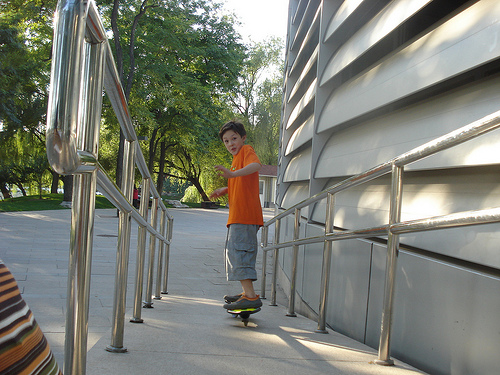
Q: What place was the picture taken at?
A: It was taken at the patio.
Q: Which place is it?
A: It is a patio.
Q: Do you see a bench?
A: No, there are no benches.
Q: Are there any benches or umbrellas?
A: No, there are no benches or umbrellas.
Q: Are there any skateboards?
A: Yes, there is a skateboard.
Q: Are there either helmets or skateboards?
A: Yes, there is a skateboard.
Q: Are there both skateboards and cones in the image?
A: No, there is a skateboard but no cones.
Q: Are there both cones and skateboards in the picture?
A: No, there is a skateboard but no cones.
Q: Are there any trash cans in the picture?
A: No, there are no trash cans.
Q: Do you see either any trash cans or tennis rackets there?
A: No, there are no trash cans or tennis rackets.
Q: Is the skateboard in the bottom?
A: Yes, the skateboard is in the bottom of the image.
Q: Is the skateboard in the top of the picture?
A: No, the skateboard is in the bottom of the image.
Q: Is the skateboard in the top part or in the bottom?
A: The skateboard is in the bottom of the image.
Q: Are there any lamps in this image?
A: No, there are no lamps.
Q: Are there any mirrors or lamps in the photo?
A: No, there are no lamps or mirrors.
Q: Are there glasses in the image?
A: No, there are no glasses.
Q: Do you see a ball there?
A: No, there are no balls.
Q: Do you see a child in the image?
A: Yes, there is a child.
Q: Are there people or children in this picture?
A: Yes, there is a child.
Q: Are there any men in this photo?
A: No, there are no men.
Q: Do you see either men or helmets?
A: No, there are no men or helmets.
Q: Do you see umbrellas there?
A: No, there are no umbrellas.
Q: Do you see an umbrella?
A: No, there are no umbrellas.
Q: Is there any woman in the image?
A: No, there are no women.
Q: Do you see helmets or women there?
A: No, there are no women or helmets.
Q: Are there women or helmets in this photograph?
A: No, there are no women or helmets.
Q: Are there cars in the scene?
A: No, there are no cars.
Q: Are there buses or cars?
A: No, there are no cars or buses.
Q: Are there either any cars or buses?
A: No, there are no cars or buses.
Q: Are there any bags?
A: No, there are no bags.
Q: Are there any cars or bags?
A: No, there are no bags or cars.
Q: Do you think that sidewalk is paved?
A: Yes, the sidewalk is paved.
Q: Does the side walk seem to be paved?
A: Yes, the side walk is paved.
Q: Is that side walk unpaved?
A: No, the side walk is paved.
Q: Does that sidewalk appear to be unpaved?
A: No, the sidewalk is paved.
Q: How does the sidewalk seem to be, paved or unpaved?
A: The sidewalk is paved.